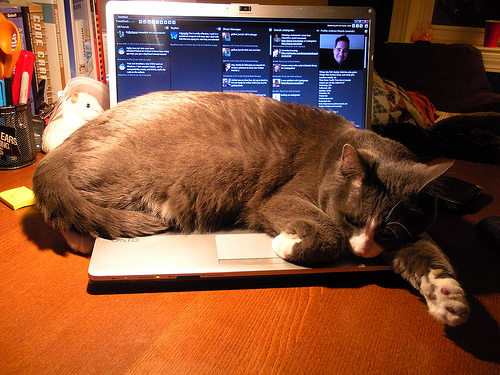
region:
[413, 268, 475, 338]
white cat paw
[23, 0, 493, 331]
cat laying on a laptop computer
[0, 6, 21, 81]
orange scissor handles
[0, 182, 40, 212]
yellow post-it notes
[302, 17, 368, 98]
picture of a man on a computer screen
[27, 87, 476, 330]
dark cat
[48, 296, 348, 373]
fake wood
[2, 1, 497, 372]
cat laying on a computer on a desk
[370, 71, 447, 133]
multiple colored blanket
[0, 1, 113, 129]
books lined up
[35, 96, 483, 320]
A gray cat with white paws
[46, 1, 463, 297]
A gray cat laying on a laptop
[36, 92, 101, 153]
A toy mouse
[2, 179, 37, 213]
A pad of yellow sticky notes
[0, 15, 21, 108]
Orange handled scissors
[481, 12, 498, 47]
A red cup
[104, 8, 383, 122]
A photo of a man on the laptop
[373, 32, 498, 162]
A chair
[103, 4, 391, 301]
An open laptop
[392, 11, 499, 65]
A window sill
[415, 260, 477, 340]
this is the cat's front left paw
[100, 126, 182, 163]
this is a cat's fur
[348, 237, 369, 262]
this is the cat's nose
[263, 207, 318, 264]
this is the cat's front right paw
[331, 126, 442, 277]
this is the cat's head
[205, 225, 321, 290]
this is the mouse pad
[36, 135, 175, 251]
this is the cat's tail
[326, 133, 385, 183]
this is the cat's right ear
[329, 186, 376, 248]
this is cats eye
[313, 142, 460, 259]
the head of a cat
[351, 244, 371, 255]
the nose of a cat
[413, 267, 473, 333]
the paw of a cat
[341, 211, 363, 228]
the eye of a cat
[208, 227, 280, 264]
a gray computer touch pad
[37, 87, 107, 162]
a white mouse figurine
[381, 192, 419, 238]
the whiskers of the cat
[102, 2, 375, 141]
a gray computer monitor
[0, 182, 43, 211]
a book of yellow post-it notes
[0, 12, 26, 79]
a pair of orange scissors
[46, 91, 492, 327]
Gray cat lying on computer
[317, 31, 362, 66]
Man's face on computer screen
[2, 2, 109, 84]
Books in the background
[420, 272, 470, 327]
White paw of cat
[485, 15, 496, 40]
Red Solo cup on couch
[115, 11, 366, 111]
Computer screen behind cat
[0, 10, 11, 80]
Pair of orange scissors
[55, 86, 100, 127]
White cat doll in background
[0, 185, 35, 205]
Post-It Notes behind cat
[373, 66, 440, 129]
Blanket on couch